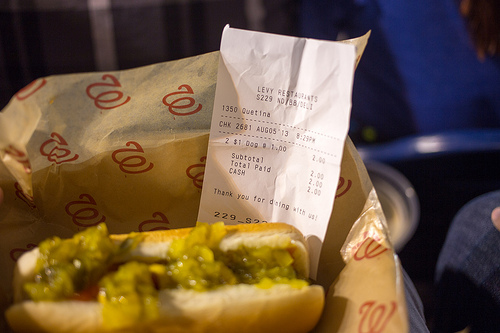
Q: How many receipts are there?
A: One.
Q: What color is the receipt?
A: White.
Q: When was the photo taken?
A: Daytime.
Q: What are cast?
A: Shadows.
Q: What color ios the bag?
A: Brown.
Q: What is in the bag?
A: Food.